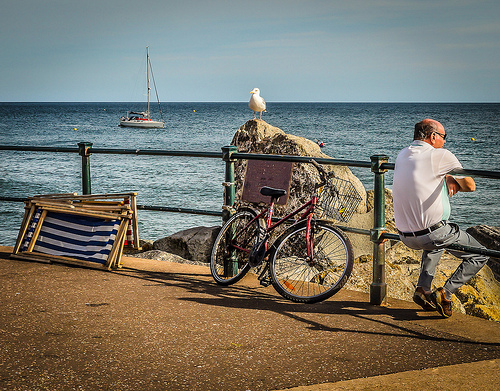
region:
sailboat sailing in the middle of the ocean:
[119, 43, 174, 134]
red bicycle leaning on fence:
[204, 157, 355, 303]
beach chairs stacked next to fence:
[13, 186, 143, 278]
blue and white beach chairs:
[12, 196, 139, 269]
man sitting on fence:
[389, 115, 489, 318]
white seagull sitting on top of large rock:
[245, 85, 267, 120]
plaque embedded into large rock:
[240, 150, 295, 210]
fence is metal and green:
[3, 135, 497, 320]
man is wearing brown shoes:
[406, 279, 457, 323]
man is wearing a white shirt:
[390, 139, 465, 228]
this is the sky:
[289, 9, 351, 50]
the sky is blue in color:
[308, 11, 353, 38]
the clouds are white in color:
[285, 41, 342, 83]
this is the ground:
[110, 285, 176, 332]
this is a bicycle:
[203, 175, 354, 302]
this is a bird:
[246, 88, 268, 114]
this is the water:
[311, 102, 352, 128]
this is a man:
[388, 107, 483, 252]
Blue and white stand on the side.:
[53, 196, 131, 266]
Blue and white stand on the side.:
[211, 290, 262, 331]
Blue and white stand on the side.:
[420, 100, 451, 135]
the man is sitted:
[390, 111, 466, 313]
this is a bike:
[212, 170, 356, 291]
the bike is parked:
[206, 168, 348, 293]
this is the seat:
[259, 184, 287, 199]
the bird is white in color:
[245, 84, 267, 117]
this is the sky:
[353, 94, 404, 143]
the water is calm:
[351, 108, 401, 150]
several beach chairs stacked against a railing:
[8, 180, 154, 283]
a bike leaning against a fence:
[181, 178, 358, 332]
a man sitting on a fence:
[388, 113, 485, 300]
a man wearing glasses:
[431, 128, 473, 153]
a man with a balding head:
[409, 116, 451, 153]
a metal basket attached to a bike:
[292, 171, 367, 230]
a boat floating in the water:
[104, 47, 183, 150]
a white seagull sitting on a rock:
[220, 73, 298, 155]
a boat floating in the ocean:
[47, 62, 234, 136]